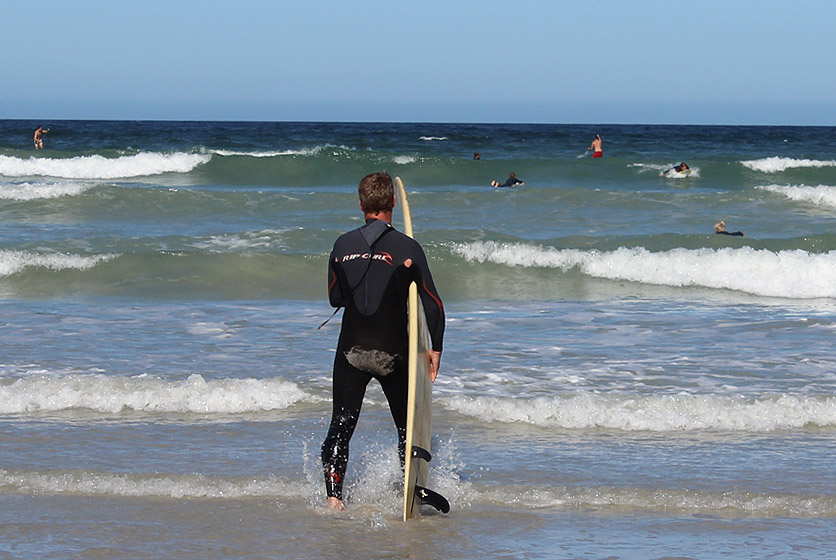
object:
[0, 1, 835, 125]
sky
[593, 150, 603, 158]
shorts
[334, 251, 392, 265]
letters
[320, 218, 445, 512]
wet suit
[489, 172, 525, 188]
person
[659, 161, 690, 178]
person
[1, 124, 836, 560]
water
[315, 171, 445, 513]
man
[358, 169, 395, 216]
hair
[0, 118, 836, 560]
ocean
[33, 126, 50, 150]
surfer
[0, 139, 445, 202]
wave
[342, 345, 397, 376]
sand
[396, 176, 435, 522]
surfboard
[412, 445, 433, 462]
fin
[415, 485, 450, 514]
fin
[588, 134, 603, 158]
man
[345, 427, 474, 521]
water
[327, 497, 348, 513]
feet